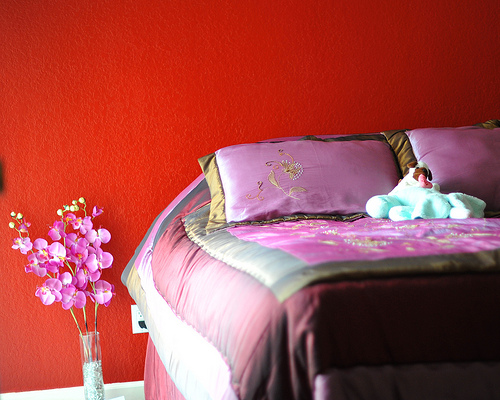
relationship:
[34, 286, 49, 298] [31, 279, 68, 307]
flower pedal adorning flower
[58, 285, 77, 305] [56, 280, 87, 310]
flower pedal adorning flower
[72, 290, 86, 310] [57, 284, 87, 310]
flower pedal adorning flower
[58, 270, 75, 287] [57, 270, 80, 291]
flower pedal adorning flower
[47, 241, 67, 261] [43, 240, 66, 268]
flower pedal adorning flower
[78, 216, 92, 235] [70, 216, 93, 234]
flower pedal adorning flower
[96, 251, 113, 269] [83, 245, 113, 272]
flower pedal adorning flower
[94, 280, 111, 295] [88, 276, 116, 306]
flower pedal adorning flower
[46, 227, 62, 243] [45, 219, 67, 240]
flower pedal adorning flower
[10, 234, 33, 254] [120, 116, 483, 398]
flower standing next to bed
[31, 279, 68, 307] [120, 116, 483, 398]
flower standing next to bed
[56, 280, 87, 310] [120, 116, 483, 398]
flower standing next to bed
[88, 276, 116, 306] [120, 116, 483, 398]
flower standing next to bed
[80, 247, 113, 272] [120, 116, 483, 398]
flower standing next to bed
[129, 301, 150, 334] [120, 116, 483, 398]
electrical outlet mounted behind bed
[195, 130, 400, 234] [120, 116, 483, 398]
pillow lying on top of bed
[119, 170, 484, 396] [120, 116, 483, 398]
blanket lying on top of bed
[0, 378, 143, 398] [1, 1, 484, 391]
wainscoting adorning wall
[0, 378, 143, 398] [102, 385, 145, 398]
wainscoting separating floor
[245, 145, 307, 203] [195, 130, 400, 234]
decoration adorning pillow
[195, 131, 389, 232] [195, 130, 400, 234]
border adorning pillow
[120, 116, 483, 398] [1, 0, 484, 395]
bed standing inside room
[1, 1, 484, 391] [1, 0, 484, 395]
wall supporting room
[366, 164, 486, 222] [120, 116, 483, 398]
toy sitting on top of bed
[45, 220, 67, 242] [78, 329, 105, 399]
flower standing in vase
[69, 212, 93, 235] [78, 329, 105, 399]
flower standing in vase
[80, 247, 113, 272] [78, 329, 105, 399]
flower standing in vase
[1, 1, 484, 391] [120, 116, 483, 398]
wall behind bed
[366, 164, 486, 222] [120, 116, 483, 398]
toy on bed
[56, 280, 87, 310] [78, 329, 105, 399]
flower in vase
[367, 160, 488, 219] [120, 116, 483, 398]
bear on bed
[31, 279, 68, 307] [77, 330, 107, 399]
flower in vase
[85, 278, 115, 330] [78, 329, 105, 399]
flower in vase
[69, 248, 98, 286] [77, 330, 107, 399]
flower in vase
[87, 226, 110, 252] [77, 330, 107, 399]
flower in vase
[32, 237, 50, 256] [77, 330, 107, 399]
flower in vase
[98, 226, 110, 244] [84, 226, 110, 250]
petal on flower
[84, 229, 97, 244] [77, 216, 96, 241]
petal on flower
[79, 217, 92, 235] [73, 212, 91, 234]
petal on flower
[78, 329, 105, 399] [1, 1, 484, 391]
vase standing in front of wall